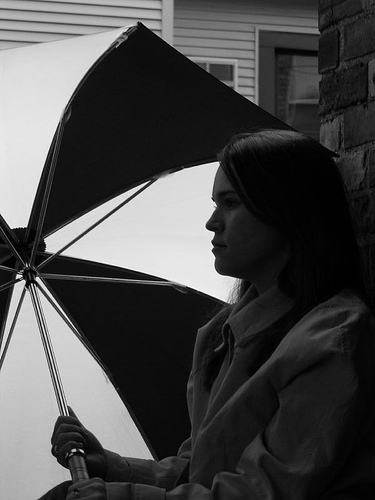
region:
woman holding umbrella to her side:
[39, 93, 330, 464]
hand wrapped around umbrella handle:
[30, 401, 110, 469]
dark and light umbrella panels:
[1, 153, 174, 395]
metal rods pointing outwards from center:
[1, 155, 151, 367]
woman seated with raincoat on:
[165, 121, 340, 436]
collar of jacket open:
[180, 287, 338, 393]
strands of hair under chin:
[190, 267, 262, 312]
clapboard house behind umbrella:
[107, 1, 324, 125]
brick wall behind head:
[312, 1, 372, 198]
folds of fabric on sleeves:
[141, 448, 331, 491]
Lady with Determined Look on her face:
[187, 119, 373, 317]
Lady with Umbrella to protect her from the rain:
[4, 6, 372, 498]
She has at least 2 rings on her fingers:
[49, 404, 104, 498]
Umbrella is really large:
[2, 3, 370, 497]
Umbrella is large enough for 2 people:
[4, 4, 370, 496]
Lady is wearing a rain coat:
[43, 122, 370, 495]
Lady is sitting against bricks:
[3, 3, 369, 498]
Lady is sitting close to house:
[3, 2, 370, 497]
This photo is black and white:
[3, 5, 372, 496]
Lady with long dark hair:
[198, 121, 369, 393]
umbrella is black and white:
[9, 279, 207, 471]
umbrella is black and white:
[22, 296, 189, 466]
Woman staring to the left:
[196, 116, 361, 311]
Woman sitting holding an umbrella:
[0, 17, 373, 499]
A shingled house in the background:
[0, 0, 321, 124]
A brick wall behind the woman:
[314, 0, 374, 225]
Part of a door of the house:
[259, 32, 323, 128]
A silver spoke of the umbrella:
[42, 257, 173, 305]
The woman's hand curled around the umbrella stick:
[45, 402, 117, 476]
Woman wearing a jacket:
[106, 282, 373, 498]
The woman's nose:
[205, 208, 234, 233]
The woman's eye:
[209, 191, 249, 213]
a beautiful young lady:
[51, 128, 373, 499]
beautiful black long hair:
[215, 128, 353, 303]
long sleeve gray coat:
[103, 285, 373, 498]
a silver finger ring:
[69, 486, 82, 498]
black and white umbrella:
[0, 19, 341, 497]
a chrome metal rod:
[27, 283, 85, 467]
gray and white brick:
[315, 0, 373, 317]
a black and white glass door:
[257, 25, 319, 149]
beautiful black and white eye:
[221, 196, 241, 211]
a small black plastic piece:
[20, 266, 39, 289]